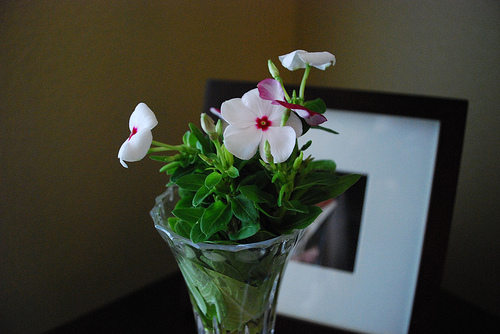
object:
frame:
[202, 77, 471, 333]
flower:
[117, 49, 342, 218]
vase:
[152, 190, 334, 334]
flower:
[117, 103, 162, 169]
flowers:
[258, 79, 329, 126]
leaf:
[192, 182, 223, 207]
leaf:
[202, 202, 232, 239]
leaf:
[182, 131, 190, 146]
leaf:
[301, 174, 362, 204]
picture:
[202, 80, 468, 334]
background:
[11, 4, 500, 84]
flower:
[221, 87, 303, 163]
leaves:
[174, 173, 208, 189]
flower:
[280, 50, 335, 71]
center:
[255, 115, 272, 131]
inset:
[243, 109, 437, 334]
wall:
[3, 6, 118, 301]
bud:
[201, 113, 216, 135]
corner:
[235, 0, 329, 48]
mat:
[368, 110, 427, 334]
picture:
[287, 170, 367, 272]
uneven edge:
[161, 232, 291, 252]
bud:
[264, 140, 272, 155]